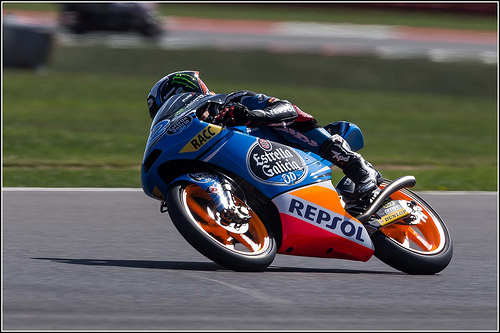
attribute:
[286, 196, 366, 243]
writing — blue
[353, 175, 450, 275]
wheel — black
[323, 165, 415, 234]
pipe — silver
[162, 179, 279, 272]
wheel — black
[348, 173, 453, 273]
wheel — black, orange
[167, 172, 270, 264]
wheel — black, orange